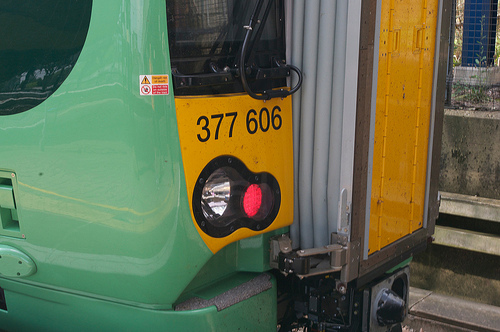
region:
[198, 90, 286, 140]
2 different numbers can be read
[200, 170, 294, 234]
a bright red light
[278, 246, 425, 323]
bottom part of a bus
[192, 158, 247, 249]
a light that is off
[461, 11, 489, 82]
a blue window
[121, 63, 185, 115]
a small warning sign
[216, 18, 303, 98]
a black wire on window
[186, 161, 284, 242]
a light on a train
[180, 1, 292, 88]
part of a windshield wiper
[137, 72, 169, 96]
a sticker on the train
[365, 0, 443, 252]
a yellow metal door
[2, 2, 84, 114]
a side window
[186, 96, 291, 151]
a number on the train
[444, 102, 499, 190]
a gray concrete wall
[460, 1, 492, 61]
a blue tile post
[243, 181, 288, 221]
a red light on a train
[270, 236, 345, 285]
a expansion lock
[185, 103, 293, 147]
The numbers on the train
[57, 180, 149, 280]
The color of the bus is cyan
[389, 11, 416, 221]
The color of the door is yellow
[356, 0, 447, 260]
The door to the train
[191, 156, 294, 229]
The head light on the bus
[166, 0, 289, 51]
The window on the train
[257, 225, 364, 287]
The latch to the door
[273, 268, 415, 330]
The mechanics of the train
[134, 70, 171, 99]
A warning sticker on the train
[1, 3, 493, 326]
A train on the tracks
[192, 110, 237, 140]
The black number 377.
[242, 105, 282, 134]
The black number 606.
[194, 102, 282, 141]
The black number 377 606.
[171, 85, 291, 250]
A yellow panel with a number and lights on it.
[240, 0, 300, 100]
A black hose above the number.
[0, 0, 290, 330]
A green panel of a train.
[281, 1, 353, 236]
5 grey panels to the right of a yellow number panel.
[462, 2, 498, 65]
A black and blue tiled wall.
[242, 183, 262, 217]
A red round light on a bus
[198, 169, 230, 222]
A silver light on a bus.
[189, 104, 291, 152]
black text on front of train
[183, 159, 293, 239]
headlights on front of train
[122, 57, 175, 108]
safety sticker on side of train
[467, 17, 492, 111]
small green plant growing behind train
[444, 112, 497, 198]
grey concrete wall behind train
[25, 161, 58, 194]
black speck on side of train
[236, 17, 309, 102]
black wiring on front of train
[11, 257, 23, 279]
small black bolts on side of train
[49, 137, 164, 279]
reflection on side of train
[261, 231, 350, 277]
large silver metal machinery parts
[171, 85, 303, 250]
yellow section of train front with black numbers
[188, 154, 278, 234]
Lights on a bus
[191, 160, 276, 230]
Lights on a bus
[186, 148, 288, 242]
Lights on a bus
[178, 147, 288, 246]
Lights on a bus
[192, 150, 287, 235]
Lights on a bus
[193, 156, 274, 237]
Lights on a bus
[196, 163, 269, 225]
Lights on a bus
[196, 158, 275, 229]
Lights on a bus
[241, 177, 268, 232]
The red back brake light.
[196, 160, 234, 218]
The clear light on the back.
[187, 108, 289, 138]
The six digit number on the van.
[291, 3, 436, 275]
The open door on the bus.